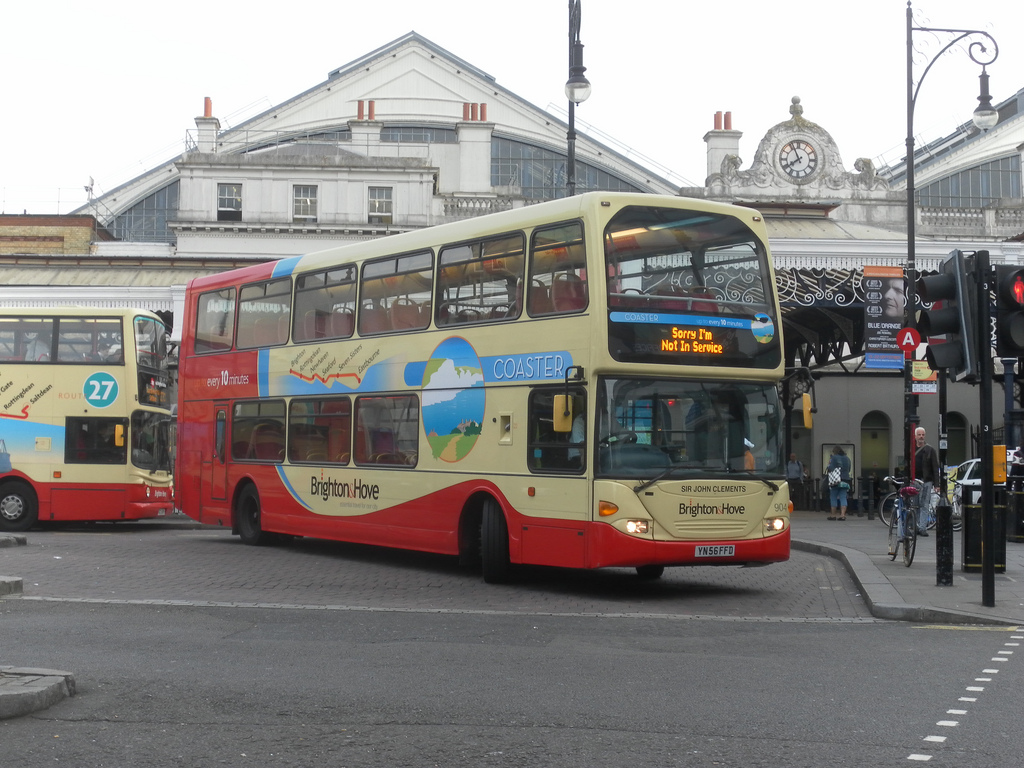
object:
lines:
[918, 731, 948, 746]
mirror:
[547, 385, 575, 437]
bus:
[169, 182, 794, 588]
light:
[1002, 268, 1024, 307]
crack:
[25, 707, 1021, 760]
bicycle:
[882, 470, 928, 568]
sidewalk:
[783, 506, 1024, 629]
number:
[769, 501, 782, 514]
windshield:
[591, 372, 789, 481]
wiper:
[629, 463, 722, 493]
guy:
[909, 424, 941, 537]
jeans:
[915, 481, 932, 532]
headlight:
[622, 518, 649, 535]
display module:
[607, 304, 788, 370]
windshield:
[600, 203, 780, 372]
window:
[210, 176, 249, 230]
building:
[0, 250, 433, 327]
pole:
[972, 252, 999, 612]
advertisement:
[394, 330, 592, 477]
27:
[80, 367, 119, 406]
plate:
[687, 541, 741, 561]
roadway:
[0, 518, 1016, 768]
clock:
[775, 138, 822, 181]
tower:
[703, 87, 898, 197]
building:
[167, 121, 440, 262]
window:
[317, 126, 350, 144]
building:
[0, 211, 118, 254]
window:
[228, 396, 286, 466]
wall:
[176, 165, 436, 225]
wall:
[72, 38, 680, 236]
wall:
[343, 144, 463, 187]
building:
[66, 30, 687, 244]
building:
[674, 91, 921, 233]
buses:
[0, 294, 183, 528]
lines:
[931, 716, 959, 730]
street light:
[903, 21, 1004, 147]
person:
[819, 438, 855, 522]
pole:
[896, 9, 924, 574]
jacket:
[911, 445, 943, 488]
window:
[515, 208, 598, 330]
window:
[436, 219, 524, 334]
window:
[353, 248, 433, 343]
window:
[230, 273, 302, 356]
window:
[287, 256, 359, 348]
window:
[189, 286, 239, 357]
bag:
[822, 463, 842, 488]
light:
[561, 40, 593, 107]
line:
[904, 749, 932, 766]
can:
[958, 476, 1010, 575]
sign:
[655, 321, 732, 358]